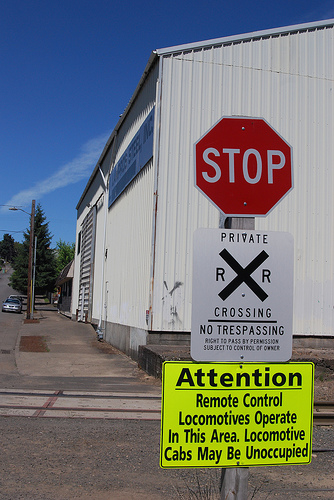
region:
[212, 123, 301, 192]
a sign board saying stop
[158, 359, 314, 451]
a sign warning post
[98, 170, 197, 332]
workshop are present on the image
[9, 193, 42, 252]
pole and a street light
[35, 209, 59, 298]
trees are on the image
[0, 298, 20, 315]
a car is on the image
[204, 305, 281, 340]
no tresspassing sign post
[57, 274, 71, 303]
a shop is seen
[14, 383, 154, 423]
slubs are on gtghe ground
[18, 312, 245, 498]
a beautiful nice short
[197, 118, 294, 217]
a red octagonal stop sign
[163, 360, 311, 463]
a yellow-green sign that warns of railroads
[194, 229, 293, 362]
black and white railroad crossing sign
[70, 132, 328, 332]
large white building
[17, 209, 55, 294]
tall evergreen tree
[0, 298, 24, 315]
car parked along a curb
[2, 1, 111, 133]
sky is blue and mostly cloudless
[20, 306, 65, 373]
sidewalk in front of building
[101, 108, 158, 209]
a sign on the side of a building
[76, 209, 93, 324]
a garage door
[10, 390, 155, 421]
a railroad track passes by a building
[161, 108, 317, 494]
three signs hang on a pole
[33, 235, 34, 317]
a tall metal pole stands on the sidewalk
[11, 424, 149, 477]
gravel litters the ground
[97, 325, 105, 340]
a gas meter is attached to the side of the building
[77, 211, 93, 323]
a shuttered door faces the street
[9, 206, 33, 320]
a street light towers over a parked car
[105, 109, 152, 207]
a blue sign hangs on the building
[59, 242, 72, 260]
a green tree peeks over a roof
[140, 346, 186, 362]
a concrete platform stick out from a building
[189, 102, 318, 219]
a stop sign sits atop a pole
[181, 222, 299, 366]
a black and white railroad sign is in the middle of the pole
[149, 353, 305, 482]
a yellow caution sign is on the bottom of the pole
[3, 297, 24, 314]
a silver sedan is parked on the curb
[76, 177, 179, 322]
a white building is behind the signs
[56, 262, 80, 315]
a store is next to a white building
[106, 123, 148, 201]
the white building has a blue sign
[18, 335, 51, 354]
a brick section in the sidewalk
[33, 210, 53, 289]
a tall pine tall is next to the street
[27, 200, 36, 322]
a tall wooden pole supports streetlight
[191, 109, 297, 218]
the stop sign is red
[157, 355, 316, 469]
the sign is neon green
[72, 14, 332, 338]
the building is white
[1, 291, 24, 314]
there are two cars parked on the street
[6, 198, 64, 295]
the tree is a pine tree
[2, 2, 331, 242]
the sky is blue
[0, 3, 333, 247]
the sky is clear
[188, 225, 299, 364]
the white sign indicates railroad crossing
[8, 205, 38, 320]
the light pole is behind the electricity pole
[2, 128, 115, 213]
the cloud is white